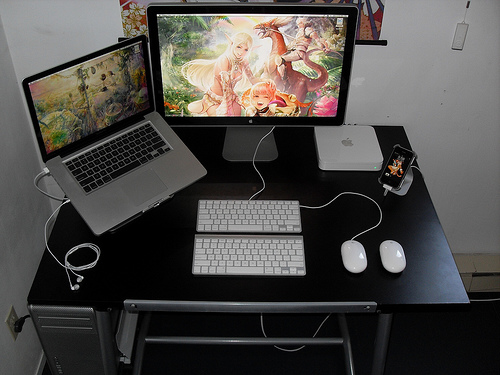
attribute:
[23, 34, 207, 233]
laptop — grey, black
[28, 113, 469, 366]
computer desk — black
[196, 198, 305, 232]
keyboard — grey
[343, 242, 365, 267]
computer mouse — corded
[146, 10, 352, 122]
computer monitor — black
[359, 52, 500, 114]
wall — white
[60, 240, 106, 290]
ear bud headphones — silver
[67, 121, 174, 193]
laptop keys — black